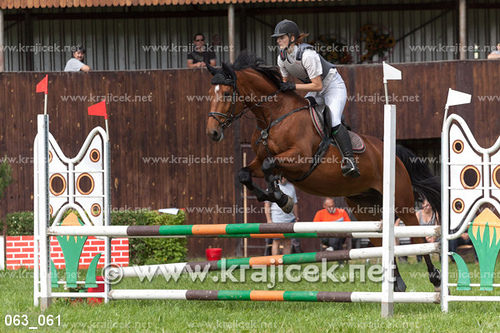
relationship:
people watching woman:
[59, 34, 213, 74] [271, 18, 360, 178]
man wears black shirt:
[186, 35, 219, 72] [187, 52, 220, 64]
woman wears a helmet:
[271, 18, 360, 178] [271, 17, 301, 39]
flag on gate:
[85, 95, 110, 118] [33, 115, 111, 302]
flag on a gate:
[446, 89, 473, 107] [441, 113, 500, 313]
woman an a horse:
[271, 18, 360, 178] [202, 57, 441, 293]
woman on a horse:
[271, 18, 360, 178] [202, 57, 441, 293]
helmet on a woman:
[271, 17, 301, 39] [271, 18, 360, 178]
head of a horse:
[206, 63, 248, 136] [202, 57, 441, 293]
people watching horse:
[59, 34, 213, 74] [202, 57, 441, 293]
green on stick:
[159, 225, 192, 234] [50, 220, 383, 237]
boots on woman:
[331, 123, 360, 173] [271, 18, 360, 178]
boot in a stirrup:
[331, 123, 360, 173] [339, 154, 356, 176]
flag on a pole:
[37, 76, 51, 93] [43, 96, 50, 309]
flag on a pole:
[383, 59, 402, 84] [383, 106, 397, 314]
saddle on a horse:
[307, 102, 367, 154] [202, 57, 441, 293]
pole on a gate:
[43, 96, 50, 309] [33, 115, 111, 302]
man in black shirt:
[186, 35, 219, 72] [187, 52, 220, 64]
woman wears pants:
[271, 18, 360, 178] [325, 65, 348, 121]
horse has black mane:
[202, 57, 441, 293] [215, 56, 292, 99]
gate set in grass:
[33, 115, 111, 302] [1, 257, 500, 331]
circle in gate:
[75, 171, 97, 197] [33, 115, 111, 302]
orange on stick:
[190, 225, 226, 239] [50, 220, 383, 237]